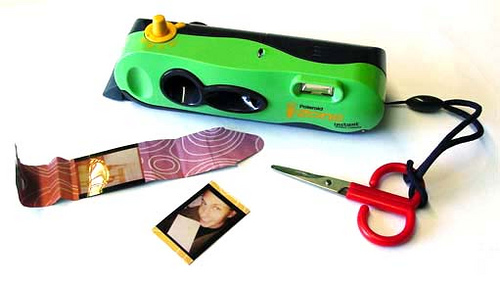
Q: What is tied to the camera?
A: Red scissors.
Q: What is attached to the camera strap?
A: Scissors.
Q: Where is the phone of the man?
A: Counter.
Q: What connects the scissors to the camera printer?
A: Camera strap.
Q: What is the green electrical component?
A: Image printer.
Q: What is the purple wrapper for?
A: Small pictures.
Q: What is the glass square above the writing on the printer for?
A: Flash.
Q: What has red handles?
A: Small scissors.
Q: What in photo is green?
A: Polaroid camera.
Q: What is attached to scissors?
A: Black string.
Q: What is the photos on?
A: Polaroid strip.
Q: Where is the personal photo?
A: Below the camera.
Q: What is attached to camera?
A: Pair of scissors.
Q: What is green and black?
A: A camera.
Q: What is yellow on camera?
A: A button.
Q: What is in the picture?
A: An instant camera.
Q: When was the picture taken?
A: Daytime.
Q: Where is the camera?
A: Table.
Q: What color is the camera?
A: Green and black.